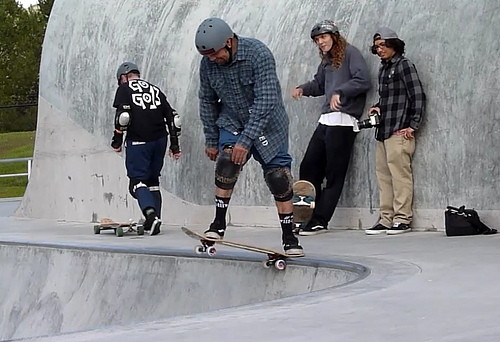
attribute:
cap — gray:
[367, 25, 404, 40]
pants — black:
[298, 120, 363, 224]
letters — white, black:
[126, 78, 148, 112]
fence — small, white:
[3, 154, 31, 185]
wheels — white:
[191, 243, 218, 256]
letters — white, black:
[132, 90, 147, 112]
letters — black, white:
[143, 90, 149, 104]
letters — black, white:
[149, 85, 158, 108]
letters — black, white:
[129, 80, 140, 91]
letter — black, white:
[126, 75, 161, 112]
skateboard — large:
[177, 217, 316, 291]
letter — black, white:
[132, 87, 147, 112]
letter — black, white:
[143, 91, 152, 105]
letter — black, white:
[137, 77, 152, 92]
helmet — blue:
[196, 20, 233, 46]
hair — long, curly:
[322, 24, 347, 71]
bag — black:
[422, 191, 489, 232]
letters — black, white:
[126, 81, 173, 130]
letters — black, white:
[126, 76, 164, 112]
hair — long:
[329, 30, 354, 68]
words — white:
[116, 78, 156, 108]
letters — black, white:
[125, 75, 175, 122]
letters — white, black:
[123, 75, 174, 119]